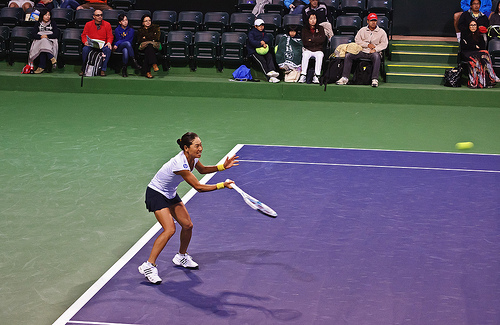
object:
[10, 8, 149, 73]
people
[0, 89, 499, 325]
match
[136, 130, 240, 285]
player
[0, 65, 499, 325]
court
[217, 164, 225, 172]
bands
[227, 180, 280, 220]
racket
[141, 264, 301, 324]
shadow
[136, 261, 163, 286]
shoes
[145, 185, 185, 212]
skirt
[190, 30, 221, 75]
seats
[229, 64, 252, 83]
bag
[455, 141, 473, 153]
ball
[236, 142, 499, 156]
lines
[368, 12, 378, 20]
cap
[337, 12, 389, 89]
person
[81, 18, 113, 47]
sweater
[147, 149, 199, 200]
jersey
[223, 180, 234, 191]
hand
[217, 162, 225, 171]
wrists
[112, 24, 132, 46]
shirt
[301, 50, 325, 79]
pants